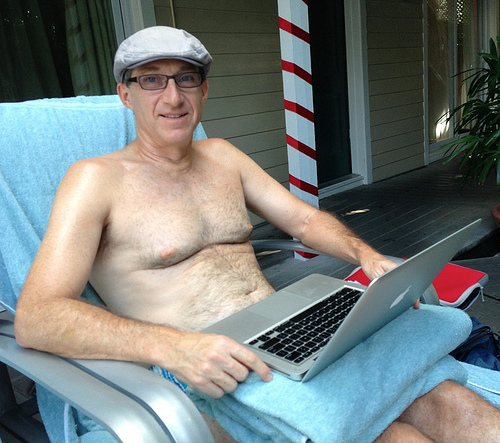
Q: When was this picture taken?
A: Daytime.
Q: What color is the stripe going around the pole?
A: Red.